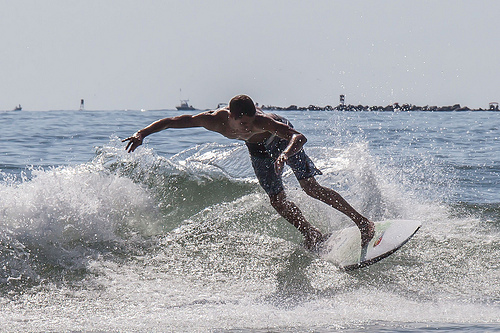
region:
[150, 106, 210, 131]
The left arm of the surfer.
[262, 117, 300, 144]
The right arm of the surfer.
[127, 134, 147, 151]
The left hand of the surfer.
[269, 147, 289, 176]
The right hand of the surfer.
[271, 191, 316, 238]
The left leg of the surfer.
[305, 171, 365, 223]
The right leg of the surfer.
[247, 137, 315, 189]
The shorts the surfer is wearing.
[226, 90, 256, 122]
The short hair of the surfer.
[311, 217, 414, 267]
The surfboard the surfer is on.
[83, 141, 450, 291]
The waves the surfer is riding.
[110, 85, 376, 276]
a man riding a surfboard.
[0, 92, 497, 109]
a section off land off in the distance.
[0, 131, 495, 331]
a wave in the ocean.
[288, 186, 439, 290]
a white surfboard.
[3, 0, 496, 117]
a hazy gray sky.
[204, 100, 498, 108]
an island across a body of water.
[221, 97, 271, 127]
a man with dark hair.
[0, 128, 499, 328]
a wave in water.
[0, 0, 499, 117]
an open sky near water.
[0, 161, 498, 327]
a foamy wave of water.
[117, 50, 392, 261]
surfer in the water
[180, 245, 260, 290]
water next to surfer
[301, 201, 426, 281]
board under the man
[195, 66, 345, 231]
man with no shirt on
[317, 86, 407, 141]
land in the background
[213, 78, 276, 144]
head of the surfer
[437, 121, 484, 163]
still water behind surfer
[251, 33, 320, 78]
sky above the land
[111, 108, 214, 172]
arm of the man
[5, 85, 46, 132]
boat in the distance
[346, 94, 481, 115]
large rocks beside water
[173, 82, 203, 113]
large boat sailing on water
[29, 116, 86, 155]
small ripples on surface of water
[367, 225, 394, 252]
design on top of surfboard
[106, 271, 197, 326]
small wave covered in white sea foam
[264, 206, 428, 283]
white and black surfboard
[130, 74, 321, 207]
man in blue swim shorts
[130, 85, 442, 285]
surfer riding wave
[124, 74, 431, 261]
shirtless man on surfboard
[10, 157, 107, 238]
white sea foam splashing in air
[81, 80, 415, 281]
surfer on white surfboard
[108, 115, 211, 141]
right arm of surfer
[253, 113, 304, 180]
left arm of surfer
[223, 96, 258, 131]
head of surfer on board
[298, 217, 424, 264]
white surfboard in water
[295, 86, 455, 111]
trees in the back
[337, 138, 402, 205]
waves of water splashing up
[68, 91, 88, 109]
tower in the distance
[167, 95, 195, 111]
boat in the water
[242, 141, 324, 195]
swim trunks on surfer